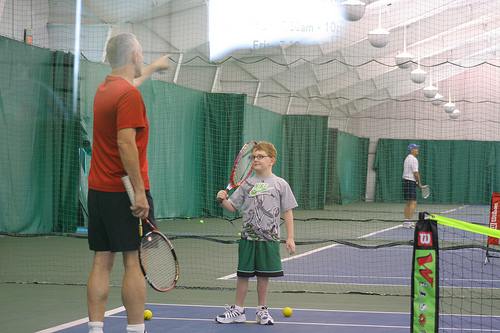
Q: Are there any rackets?
A: Yes, there is a racket.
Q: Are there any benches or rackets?
A: Yes, there is a racket.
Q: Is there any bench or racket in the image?
A: Yes, there is a racket.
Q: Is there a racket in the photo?
A: Yes, there is a racket.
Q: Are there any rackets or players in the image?
A: Yes, there is a racket.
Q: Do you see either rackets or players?
A: Yes, there is a racket.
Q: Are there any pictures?
A: No, there are no pictures.